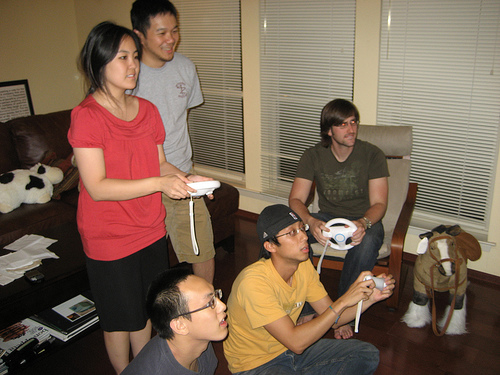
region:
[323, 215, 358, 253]
steering wheel for wii console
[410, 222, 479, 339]
stuffed horse with saddle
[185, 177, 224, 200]
steering wheel for wii console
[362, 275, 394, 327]
controller for wii console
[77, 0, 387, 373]
group of friends engaged in playing video game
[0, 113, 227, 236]
brown couch against wall of room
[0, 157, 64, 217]
stuffed white cow with black spots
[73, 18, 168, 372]
woman in red shirt and black skirt playing wii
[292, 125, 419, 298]
brown wooden framed chair with beige cushion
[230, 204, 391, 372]
man in backwards cap focused on wii game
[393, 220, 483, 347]
a toy horse in the living room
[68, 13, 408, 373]
a group of people playing video games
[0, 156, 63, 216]
a stuffed animal on a couch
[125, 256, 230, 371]
a man with dark hair and glasses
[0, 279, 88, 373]
books sitting on a coffee table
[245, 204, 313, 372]
a man wearing a yellow shirt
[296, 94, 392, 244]
a man with light brown hair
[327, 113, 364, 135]
a man with red eyes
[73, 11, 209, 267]
a woman holding a video game controller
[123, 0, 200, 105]
a person smiling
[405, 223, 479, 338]
horse on the guy's side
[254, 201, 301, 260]
man has a backwards cap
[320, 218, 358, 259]
man is holding steering wheel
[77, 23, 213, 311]
woman is playing and smiling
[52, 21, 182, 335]
woman has a red shirt on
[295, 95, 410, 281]
man is sitting on chair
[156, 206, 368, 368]
two guy's wearing glasses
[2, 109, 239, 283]
couch is in the background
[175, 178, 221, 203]
controllers are big and white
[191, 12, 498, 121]
blinds are close behind them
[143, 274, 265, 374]
Man with black hair and glasses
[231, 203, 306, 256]
Man with a black hat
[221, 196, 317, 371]
Man in a yellow shirt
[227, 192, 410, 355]
Man holding a Wii remote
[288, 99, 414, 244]
Man with brown hair playing Wii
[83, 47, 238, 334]
Woman in a red shirt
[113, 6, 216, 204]
Man in a gray shirt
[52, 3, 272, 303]
Man and woman standing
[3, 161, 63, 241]
Cow on a couch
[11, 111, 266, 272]
Brown couch in a living room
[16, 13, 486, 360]
7 young men and women playing video games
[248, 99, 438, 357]
two young men playing video game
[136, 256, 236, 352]
young man with glasses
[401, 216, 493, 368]
toy horse on floor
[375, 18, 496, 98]
white blinds covering window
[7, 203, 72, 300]
papers on coffee table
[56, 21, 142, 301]
young Asian woman wearing pink shirt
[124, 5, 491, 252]
three windows with white blinds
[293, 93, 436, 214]
man sitting in chair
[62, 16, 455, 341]
young people having fun